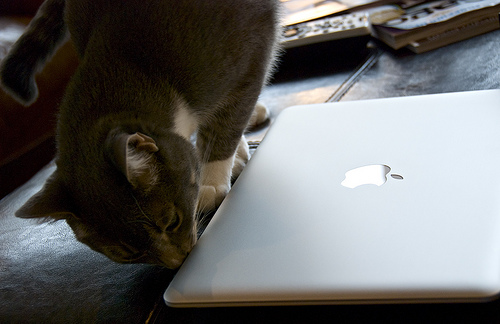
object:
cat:
[2, 4, 280, 268]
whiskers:
[188, 171, 225, 235]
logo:
[338, 163, 404, 193]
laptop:
[163, 88, 499, 311]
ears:
[108, 129, 163, 201]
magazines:
[392, 16, 500, 59]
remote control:
[278, 2, 385, 50]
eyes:
[159, 207, 185, 236]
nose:
[160, 254, 185, 269]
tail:
[3, 0, 71, 106]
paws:
[192, 161, 238, 213]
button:
[284, 28, 299, 38]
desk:
[12, 85, 499, 321]